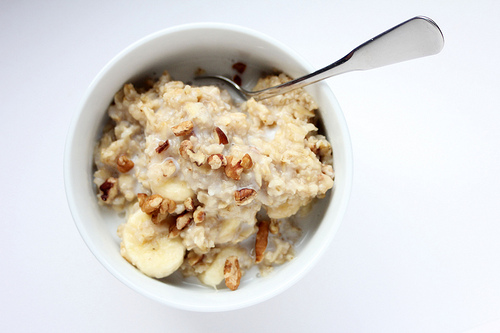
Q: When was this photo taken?
A: During a meantime.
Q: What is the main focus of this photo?
A: Food.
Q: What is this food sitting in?
A: A bowl.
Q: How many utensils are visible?
A: One.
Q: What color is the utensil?
A: Silver.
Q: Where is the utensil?
A: In the food.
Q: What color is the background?
A: White.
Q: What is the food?
A: Oatmeal with fruit and nuts.